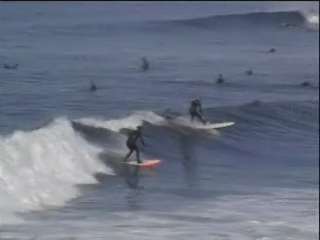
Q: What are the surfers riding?
A: Waves.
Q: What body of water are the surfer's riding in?
A: Ocean.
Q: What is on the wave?
A: Two people on surfboards.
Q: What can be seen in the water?
A: Many people swimming.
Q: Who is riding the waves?
A: Two surfers.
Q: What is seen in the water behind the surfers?
A: People swimming.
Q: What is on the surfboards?
A: Two surfers.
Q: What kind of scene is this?
A: An ocean scene.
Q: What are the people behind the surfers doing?
A: Waiting for waves.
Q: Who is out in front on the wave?
A: Person on the orange surfboard.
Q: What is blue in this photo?
A: The ocean.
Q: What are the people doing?
A: Surfing.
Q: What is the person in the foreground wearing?
A: Wetsuit.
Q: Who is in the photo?
A: Surfers.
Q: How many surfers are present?
A: Two.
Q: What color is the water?
A: Blue.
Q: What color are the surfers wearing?
A: Black.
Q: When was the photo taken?
A: During the day.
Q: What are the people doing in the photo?
A: Surfing.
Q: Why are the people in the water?
A: To surf.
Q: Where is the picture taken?
A: At the beach.